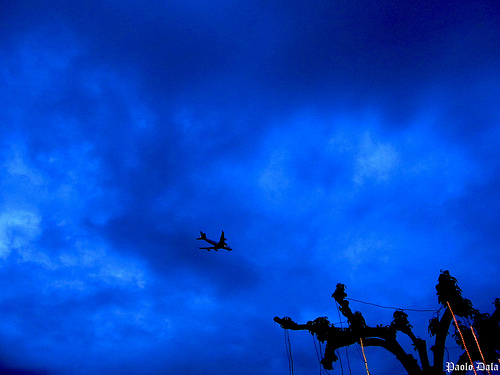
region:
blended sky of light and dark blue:
[10, 5, 485, 365]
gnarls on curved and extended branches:
[266, 265, 491, 365]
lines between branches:
[322, 286, 447, 327]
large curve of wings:
[195, 225, 225, 255]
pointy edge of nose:
[220, 240, 235, 255]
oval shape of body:
[200, 230, 230, 250]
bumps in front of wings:
[205, 227, 230, 252]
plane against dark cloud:
[185, 220, 237, 263]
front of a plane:
[226, 243, 236, 255]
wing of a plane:
[216, 226, 231, 238]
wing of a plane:
[200, 241, 220, 256]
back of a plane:
[192, 223, 212, 245]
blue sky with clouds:
[146, 42, 421, 169]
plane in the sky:
[195, 203, 249, 267]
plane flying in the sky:
[185, 213, 242, 264]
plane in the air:
[177, 206, 244, 276]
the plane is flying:
[187, 211, 259, 266]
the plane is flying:
[181, 209, 251, 269]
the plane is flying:
[170, 209, 245, 275]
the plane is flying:
[180, 199, 280, 277]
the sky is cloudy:
[290, 154, 374, 276]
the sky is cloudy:
[265, 168, 361, 255]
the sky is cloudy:
[260, 189, 352, 251]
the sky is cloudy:
[82, 254, 234, 369]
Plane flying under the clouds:
[194, 227, 236, 256]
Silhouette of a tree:
[272, 270, 486, 369]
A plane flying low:
[192, 229, 236, 254]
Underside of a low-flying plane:
[192, 227, 235, 254]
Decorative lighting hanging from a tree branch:
[356, 328, 376, 373]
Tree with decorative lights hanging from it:
[273, 265, 495, 362]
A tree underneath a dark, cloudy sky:
[275, 281, 441, 373]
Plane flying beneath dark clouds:
[191, 225, 240, 258]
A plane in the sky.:
[193, 227, 234, 254]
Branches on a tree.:
[271, 268, 498, 373]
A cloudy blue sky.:
[1, 2, 498, 372]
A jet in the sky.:
[194, 227, 231, 254]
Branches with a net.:
[271, 268, 498, 373]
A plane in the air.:
[193, 228, 232, 254]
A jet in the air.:
[193, 226, 231, 252]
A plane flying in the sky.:
[193, 227, 235, 254]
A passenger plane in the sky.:
[194, 225, 231, 252]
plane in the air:
[138, 168, 305, 286]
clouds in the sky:
[17, 45, 322, 220]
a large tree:
[247, 260, 497, 365]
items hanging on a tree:
[255, 286, 370, 373]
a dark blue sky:
[6, 29, 492, 359]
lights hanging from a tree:
[435, 292, 493, 373]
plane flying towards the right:
[171, 215, 306, 284]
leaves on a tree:
[431, 269, 478, 320]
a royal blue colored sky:
[1, 300, 86, 365]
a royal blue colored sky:
[73, 297, 174, 372]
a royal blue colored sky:
[173, 296, 276, 372]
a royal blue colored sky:
[0, 225, 94, 295]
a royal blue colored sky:
[88, 221, 167, 296]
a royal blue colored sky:
[332, 203, 393, 283]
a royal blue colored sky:
[402, 190, 498, 271]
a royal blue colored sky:
[395, 111, 497, 197]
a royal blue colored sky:
[252, 64, 391, 193]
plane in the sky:
[183, 220, 241, 257]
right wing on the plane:
[217, 225, 229, 248]